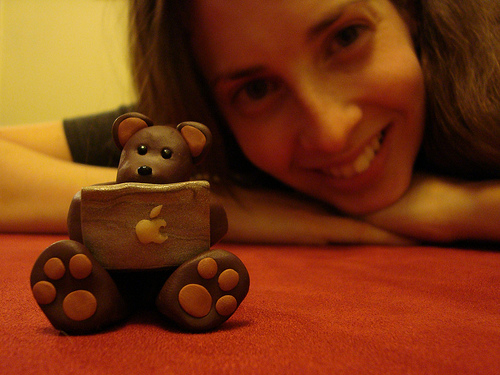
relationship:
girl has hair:
[0, 0, 500, 242] [126, 4, 496, 160]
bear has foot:
[23, 108, 258, 343] [166, 245, 250, 330]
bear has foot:
[28, 112, 251, 334] [27, 237, 125, 342]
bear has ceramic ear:
[28, 112, 251, 334] [176, 121, 211, 166]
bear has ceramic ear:
[28, 112, 251, 334] [177, 117, 209, 158]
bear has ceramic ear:
[28, 112, 251, 334] [109, 109, 151, 146]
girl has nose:
[0, 0, 500, 242] [278, 59, 363, 155]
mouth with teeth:
[295, 121, 402, 195] [306, 142, 383, 184]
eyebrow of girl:
[206, 60, 264, 95] [0, 0, 500, 242]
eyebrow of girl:
[306, 0, 380, 43] [0, 0, 500, 242]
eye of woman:
[209, 62, 290, 119] [113, 7, 497, 262]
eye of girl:
[320, 20, 377, 60] [0, 0, 500, 242]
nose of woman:
[274, 60, 366, 165] [113, 7, 497, 262]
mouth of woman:
[295, 100, 402, 195] [165, 11, 380, 196]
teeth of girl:
[304, 127, 389, 193] [0, 0, 500, 242]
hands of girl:
[216, 159, 493, 251] [0, 0, 500, 242]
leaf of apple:
[145, 200, 166, 219] [131, 200, 173, 248]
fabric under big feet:
[1, 230, 497, 373] [29, 239, 114, 334]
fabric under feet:
[1, 230, 497, 373] [156, 245, 251, 335]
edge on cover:
[67, 167, 228, 203] [60, 185, 227, 274]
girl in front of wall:
[0, 0, 500, 242] [0, 4, 124, 111]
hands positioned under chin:
[253, 187, 427, 248] [322, 180, 407, 217]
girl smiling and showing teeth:
[0, 0, 500, 242] [304, 127, 389, 178]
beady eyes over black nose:
[113, 114, 210, 186] [136, 163, 152, 178]